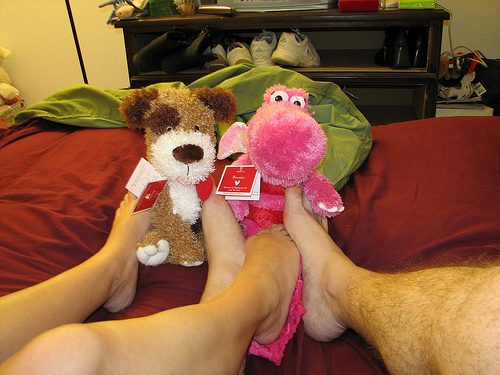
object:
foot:
[97, 189, 154, 315]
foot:
[197, 174, 247, 298]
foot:
[237, 222, 302, 346]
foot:
[279, 182, 349, 343]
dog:
[117, 84, 241, 268]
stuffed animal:
[217, 82, 347, 239]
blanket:
[11, 61, 377, 195]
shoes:
[269, 28, 322, 69]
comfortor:
[1, 115, 500, 374]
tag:
[214, 164, 261, 201]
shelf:
[105, 1, 451, 126]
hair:
[337, 246, 499, 375]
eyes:
[270, 90, 290, 103]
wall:
[0, 2, 132, 107]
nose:
[246, 109, 329, 180]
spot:
[145, 102, 180, 136]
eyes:
[165, 125, 173, 133]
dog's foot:
[134, 239, 170, 267]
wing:
[216, 120, 248, 161]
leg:
[1, 250, 117, 374]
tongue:
[175, 175, 193, 187]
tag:
[124, 155, 169, 216]